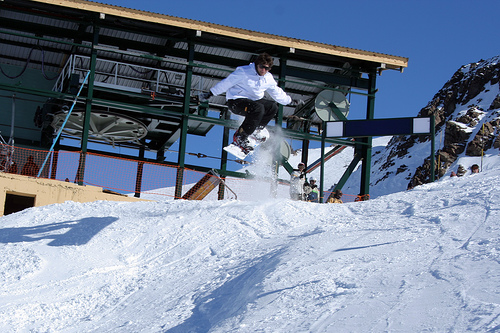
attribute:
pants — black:
[227, 95, 279, 148]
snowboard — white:
[222, 125, 270, 160]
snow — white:
[0, 156, 493, 328]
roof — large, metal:
[2, 0, 411, 139]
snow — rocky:
[300, 192, 449, 282]